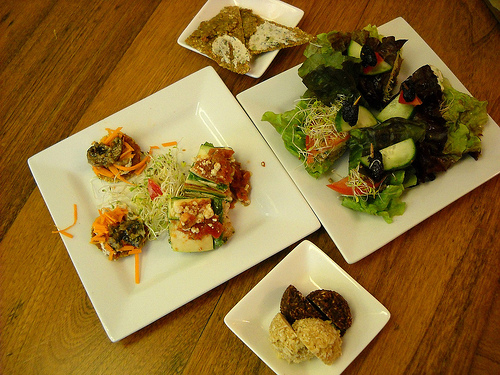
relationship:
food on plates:
[181, 22, 452, 202] [11, 4, 482, 372]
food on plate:
[259, 23, 490, 224] [237, 12, 479, 242]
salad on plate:
[95, 205, 151, 261] [28, 65, 321, 345]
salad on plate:
[116, 156, 196, 236] [28, 65, 321, 345]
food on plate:
[169, 141, 248, 193] [28, 65, 321, 345]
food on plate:
[259, 23, 490, 224] [235, 17, 499, 263]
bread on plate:
[187, 5, 314, 74] [176, 0, 305, 79]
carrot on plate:
[88, 206, 128, 241] [28, 65, 321, 345]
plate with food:
[235, 17, 499, 263] [259, 23, 490, 224]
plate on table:
[235, 17, 499, 263] [3, 3, 483, 373]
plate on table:
[28, 65, 321, 345] [3, 3, 483, 373]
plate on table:
[223, 239, 392, 374] [3, 3, 483, 373]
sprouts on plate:
[28, 65, 322, 343] [28, 65, 321, 345]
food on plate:
[259, 23, 490, 224] [233, 17, 470, 264]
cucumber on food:
[373, 136, 416, 175] [259, 23, 490, 224]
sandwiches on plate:
[83, 124, 257, 277] [28, 65, 321, 345]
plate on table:
[220, 233, 396, 373] [3, 3, 483, 373]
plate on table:
[172, 1, 309, 87] [3, 3, 483, 373]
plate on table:
[176, 0, 305, 79] [3, 3, 483, 373]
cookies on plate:
[265, 281, 355, 365] [223, 239, 392, 374]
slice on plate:
[49, 202, 82, 238] [28, 65, 321, 345]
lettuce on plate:
[113, 148, 187, 243] [28, 65, 321, 345]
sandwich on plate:
[368, 68, 440, 130] [233, 17, 470, 264]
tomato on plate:
[302, 128, 349, 166] [235, 17, 498, 265]